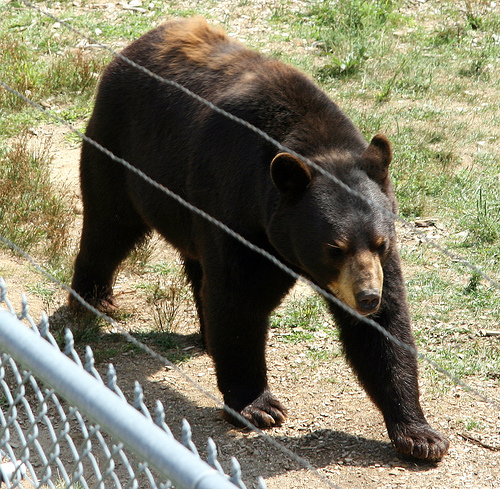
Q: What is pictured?
A: Bear.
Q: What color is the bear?
A: Brown.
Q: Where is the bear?
A: Behind the fence.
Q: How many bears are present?
A: 1.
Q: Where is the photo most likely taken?
A: Zoo.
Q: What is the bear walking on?
A: Dirt.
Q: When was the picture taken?
A: During the day.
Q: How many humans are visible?
A: Zero.